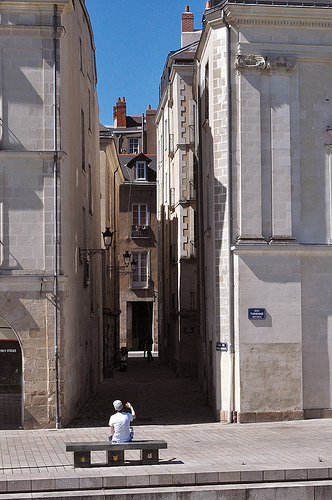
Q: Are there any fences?
A: No, there are no fences.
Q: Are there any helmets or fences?
A: No, there are no fences or helmets.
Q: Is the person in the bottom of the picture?
A: Yes, the person is in the bottom of the image.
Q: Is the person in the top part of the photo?
A: No, the person is in the bottom of the image.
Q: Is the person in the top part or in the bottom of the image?
A: The person is in the bottom of the image.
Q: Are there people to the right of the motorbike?
A: Yes, there is a person to the right of the motorbike.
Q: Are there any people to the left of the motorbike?
A: No, the person is to the right of the motorbike.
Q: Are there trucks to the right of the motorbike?
A: No, there is a person to the right of the motorbike.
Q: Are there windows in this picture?
A: Yes, there is a window.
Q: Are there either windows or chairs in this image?
A: Yes, there is a window.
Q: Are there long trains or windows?
A: Yes, there is a long window.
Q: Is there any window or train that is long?
A: Yes, the window is long.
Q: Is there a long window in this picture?
A: Yes, there is a long window.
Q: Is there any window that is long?
A: Yes, there is a window that is long.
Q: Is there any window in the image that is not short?
A: Yes, there is a long window.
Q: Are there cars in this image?
A: No, there are no cars.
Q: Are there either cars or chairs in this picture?
A: No, there are no cars or chairs.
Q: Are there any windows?
A: Yes, there is a window.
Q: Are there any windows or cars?
A: Yes, there is a window.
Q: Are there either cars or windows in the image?
A: Yes, there is a window.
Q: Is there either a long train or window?
A: Yes, there is a long window.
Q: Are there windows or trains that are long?
A: Yes, the window is long.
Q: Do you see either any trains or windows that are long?
A: Yes, the window is long.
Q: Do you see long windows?
A: Yes, there is a long window.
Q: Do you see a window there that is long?
A: Yes, there is a window that is long.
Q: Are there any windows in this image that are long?
A: Yes, there is a window that is long.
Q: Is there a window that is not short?
A: Yes, there is a long window.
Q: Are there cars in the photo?
A: No, there are no cars.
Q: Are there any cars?
A: No, there are no cars.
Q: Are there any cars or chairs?
A: No, there are no cars or chairs.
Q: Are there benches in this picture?
A: Yes, there is a bench.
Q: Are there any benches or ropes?
A: Yes, there is a bench.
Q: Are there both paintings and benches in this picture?
A: No, there is a bench but no paintings.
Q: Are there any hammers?
A: No, there are no hammers.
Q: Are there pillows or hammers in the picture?
A: No, there are no hammers or pillows.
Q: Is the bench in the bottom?
A: Yes, the bench is in the bottom of the image.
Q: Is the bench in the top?
A: No, the bench is in the bottom of the image.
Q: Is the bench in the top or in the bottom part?
A: The bench is in the bottom of the image.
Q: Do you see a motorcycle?
A: Yes, there is a motorcycle.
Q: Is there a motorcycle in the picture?
A: Yes, there is a motorcycle.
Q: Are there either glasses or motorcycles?
A: Yes, there is a motorcycle.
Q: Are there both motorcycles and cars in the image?
A: No, there is a motorcycle but no cars.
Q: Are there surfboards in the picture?
A: No, there are no surfboards.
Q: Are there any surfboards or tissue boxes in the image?
A: No, there are no surfboards or tissue boxes.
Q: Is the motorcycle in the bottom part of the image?
A: Yes, the motorcycle is in the bottom of the image.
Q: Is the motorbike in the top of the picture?
A: No, the motorbike is in the bottom of the image.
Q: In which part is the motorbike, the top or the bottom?
A: The motorbike is in the bottom of the image.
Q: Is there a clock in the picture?
A: No, there are no clocks.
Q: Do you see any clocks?
A: No, there are no clocks.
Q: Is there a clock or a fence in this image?
A: No, there are no clocks or fences.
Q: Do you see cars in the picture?
A: No, there are no cars.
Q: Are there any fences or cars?
A: No, there are no cars or fences.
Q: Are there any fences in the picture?
A: No, there are no fences.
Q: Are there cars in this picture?
A: No, there are no cars.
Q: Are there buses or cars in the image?
A: No, there are no cars or buses.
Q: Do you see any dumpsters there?
A: No, there are no dumpsters.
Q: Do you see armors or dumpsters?
A: No, there are no dumpsters or armors.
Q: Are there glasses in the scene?
A: No, there are no glasses.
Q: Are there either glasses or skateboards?
A: No, there are no glasses or skateboards.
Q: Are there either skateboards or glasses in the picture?
A: No, there are no glasses or skateboards.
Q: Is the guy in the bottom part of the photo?
A: Yes, the guy is in the bottom of the image.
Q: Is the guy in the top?
A: No, the guy is in the bottom of the image.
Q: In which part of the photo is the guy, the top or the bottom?
A: The guy is in the bottom of the image.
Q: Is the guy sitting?
A: Yes, the guy is sitting.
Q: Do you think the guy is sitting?
A: Yes, the guy is sitting.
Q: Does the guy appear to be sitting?
A: Yes, the guy is sitting.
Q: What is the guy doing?
A: The guy is sitting.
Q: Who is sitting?
A: The guy is sitting.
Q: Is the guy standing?
A: No, the guy is sitting.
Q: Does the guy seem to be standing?
A: No, the guy is sitting.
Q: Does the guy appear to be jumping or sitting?
A: The guy is sitting.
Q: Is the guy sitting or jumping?
A: The guy is sitting.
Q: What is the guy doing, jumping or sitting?
A: The guy is sitting.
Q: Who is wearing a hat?
A: The guy is wearing a hat.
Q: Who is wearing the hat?
A: The guy is wearing a hat.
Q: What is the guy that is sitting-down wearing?
A: The guy is wearing a hat.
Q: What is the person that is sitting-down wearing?
A: The guy is wearing a hat.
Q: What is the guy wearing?
A: The guy is wearing a hat.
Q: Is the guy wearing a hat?
A: Yes, the guy is wearing a hat.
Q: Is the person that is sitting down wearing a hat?
A: Yes, the guy is wearing a hat.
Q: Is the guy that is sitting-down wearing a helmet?
A: No, the guy is wearing a hat.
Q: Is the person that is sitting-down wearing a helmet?
A: No, the guy is wearing a hat.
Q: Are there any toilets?
A: No, there are no toilets.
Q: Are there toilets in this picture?
A: No, there are no toilets.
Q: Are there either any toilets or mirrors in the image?
A: No, there are no toilets or mirrors.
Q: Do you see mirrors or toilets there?
A: No, there are no toilets or mirrors.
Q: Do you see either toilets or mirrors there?
A: No, there are no toilets or mirrors.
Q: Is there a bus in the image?
A: No, there are no buses.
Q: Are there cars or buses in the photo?
A: No, there are no buses or cars.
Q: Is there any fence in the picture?
A: No, there are no fences.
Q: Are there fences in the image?
A: No, there are no fences.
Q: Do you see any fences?
A: No, there are no fences.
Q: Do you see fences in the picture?
A: No, there are no fences.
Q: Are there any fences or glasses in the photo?
A: No, there are no fences or glasses.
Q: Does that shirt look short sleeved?
A: Yes, the shirt is short sleeved.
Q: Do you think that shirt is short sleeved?
A: Yes, the shirt is short sleeved.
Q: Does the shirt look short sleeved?
A: Yes, the shirt is short sleeved.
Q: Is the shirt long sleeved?
A: No, the shirt is short sleeved.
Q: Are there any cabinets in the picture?
A: No, there are no cabinets.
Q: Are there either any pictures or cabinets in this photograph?
A: No, there are no cabinets or pictures.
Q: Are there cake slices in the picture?
A: No, there are no cake slices.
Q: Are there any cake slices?
A: No, there are no cake slices.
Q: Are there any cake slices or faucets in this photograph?
A: No, there are no cake slices or faucets.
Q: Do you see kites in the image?
A: No, there are no kites.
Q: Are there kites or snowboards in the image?
A: No, there are no kites or snowboards.